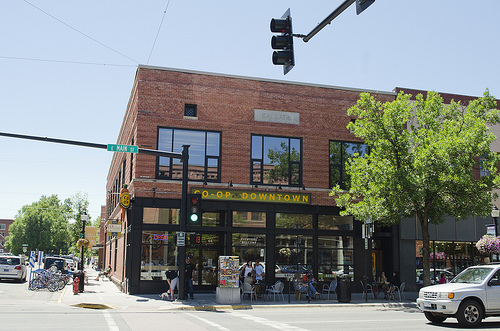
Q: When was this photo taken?
A: During the day.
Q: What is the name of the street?
A: E Main St.